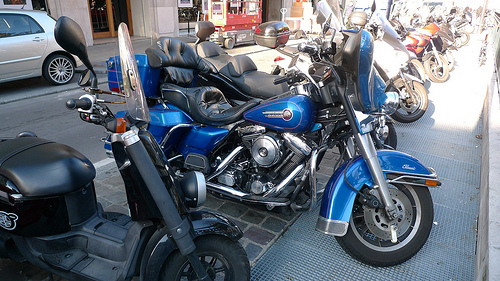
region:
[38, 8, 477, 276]
Motorcycles on side of road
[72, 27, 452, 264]
Motorcycle is blue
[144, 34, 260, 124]
Sit of motorcycle is black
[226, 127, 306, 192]
Engine of motorcycle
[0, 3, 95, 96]
Grey car parked on side of the road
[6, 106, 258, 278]
Motorcycle is black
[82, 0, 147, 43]
Double door of a building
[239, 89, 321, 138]
Gas tank of motorcycle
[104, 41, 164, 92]
Blue box behind sit of motorcycle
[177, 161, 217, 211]
Headlight of motorcycle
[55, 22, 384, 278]
motorcycles are parked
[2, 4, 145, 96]
the car is silver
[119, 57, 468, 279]
the bike is blue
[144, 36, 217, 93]
the seat is leather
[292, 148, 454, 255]
the bike has wheels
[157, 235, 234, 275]
the wheels are black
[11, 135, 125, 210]
the seat is black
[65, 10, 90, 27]
the wall is white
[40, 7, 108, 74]
the side mirror is black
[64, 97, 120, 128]
the handle is black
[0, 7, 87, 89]
silver van parked on the side of the road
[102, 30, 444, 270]
blue colored motorcycle parked on the side of the road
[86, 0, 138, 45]
wooden set of doors to a shop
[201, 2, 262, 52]
red metal cart on the street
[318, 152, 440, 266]
front wheel of a blue motorcycle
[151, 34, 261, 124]
black seat on a blue motorcycle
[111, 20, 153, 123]
windshield on a black motorscooter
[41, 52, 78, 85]
back passenger wheel on a silver van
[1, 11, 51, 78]
door of a van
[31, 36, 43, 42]
door handle on a van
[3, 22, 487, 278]
a line of motorcycles parked on the side of the road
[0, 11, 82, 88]
a car parked on the other side of the road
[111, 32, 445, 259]
a blue motorcycle parked on the side of the road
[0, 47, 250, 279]
a black motorcycle parked next to the blue one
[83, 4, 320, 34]
a line of buildings next to the road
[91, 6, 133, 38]
the front doors of a building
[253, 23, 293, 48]
a part of a motorcycle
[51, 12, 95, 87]
a side view mirror of a motorcycle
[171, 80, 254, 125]
the seat of the motorcycle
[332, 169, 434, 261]
the front window of the motorcycle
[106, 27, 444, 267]
a blue motorcycle with two seats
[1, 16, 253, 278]
a black scooter beside a motorcycle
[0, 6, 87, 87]
a silver car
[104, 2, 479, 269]
a line of motorcycles parked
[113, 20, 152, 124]
a wind shield on a scooter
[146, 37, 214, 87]
a backrest for a passenger on a motorcycle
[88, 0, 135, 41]
doors with wood borders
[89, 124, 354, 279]
parking area made of small square bricks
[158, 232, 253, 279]
a scooter tire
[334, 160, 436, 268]
a motorcycle tire